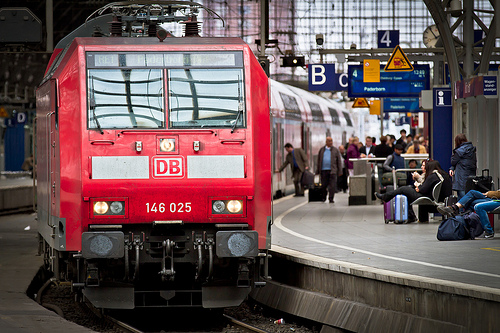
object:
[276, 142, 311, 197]
man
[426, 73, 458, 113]
sign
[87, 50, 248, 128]
windshield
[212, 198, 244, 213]
headlight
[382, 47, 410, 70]
signs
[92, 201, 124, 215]
head light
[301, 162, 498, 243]
luggage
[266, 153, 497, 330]
platform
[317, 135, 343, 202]
passenger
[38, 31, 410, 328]
train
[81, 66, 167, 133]
left windshield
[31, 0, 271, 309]
engine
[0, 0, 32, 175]
wall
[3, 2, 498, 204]
building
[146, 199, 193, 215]
id numbers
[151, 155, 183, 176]
logo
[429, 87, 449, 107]
letter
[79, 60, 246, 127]
reflections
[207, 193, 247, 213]
headlights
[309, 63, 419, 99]
letters